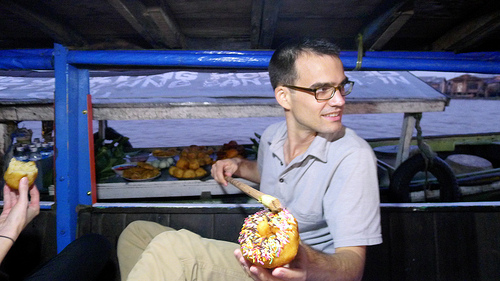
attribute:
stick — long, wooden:
[181, 160, 298, 217]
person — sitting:
[118, 52, 406, 279]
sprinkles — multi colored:
[239, 208, 293, 265]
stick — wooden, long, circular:
[221, 172, 280, 212]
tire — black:
[387, 154, 475, 202]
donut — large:
[235, 205, 305, 266]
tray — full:
[114, 160, 158, 179]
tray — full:
[141, 150, 177, 172]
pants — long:
[116, 218, 258, 280]